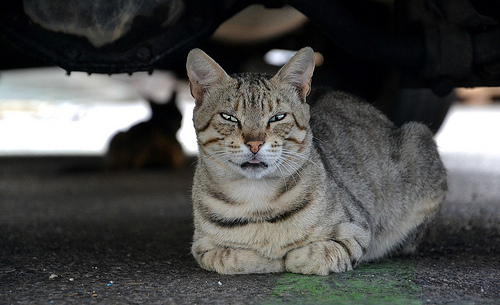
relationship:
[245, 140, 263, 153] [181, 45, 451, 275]
cat's nose on cat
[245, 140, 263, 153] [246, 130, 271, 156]
cat's nose on cat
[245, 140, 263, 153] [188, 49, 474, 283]
cat's nose on cat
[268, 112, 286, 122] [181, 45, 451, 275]
cat's eye on cat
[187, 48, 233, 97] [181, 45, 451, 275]
ear on cat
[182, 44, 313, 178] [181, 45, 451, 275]
head on cat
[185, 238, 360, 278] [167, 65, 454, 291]
feet are on cat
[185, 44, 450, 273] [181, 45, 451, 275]
cat fur on cat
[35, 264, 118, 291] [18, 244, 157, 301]
debris on asphalt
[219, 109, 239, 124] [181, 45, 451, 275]
eye of a cat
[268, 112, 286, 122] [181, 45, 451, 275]
cat's eye of a cat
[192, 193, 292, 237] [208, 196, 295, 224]
stripes on a fur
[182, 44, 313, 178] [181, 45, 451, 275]
head of a cat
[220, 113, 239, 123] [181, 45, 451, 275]
eye of a cat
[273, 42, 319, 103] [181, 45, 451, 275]
ear of a cat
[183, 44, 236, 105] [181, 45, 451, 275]
ear of a cat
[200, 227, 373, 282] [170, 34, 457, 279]
legs of a cat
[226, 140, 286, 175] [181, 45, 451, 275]
mouth of a cat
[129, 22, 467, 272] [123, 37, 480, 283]
body of a cat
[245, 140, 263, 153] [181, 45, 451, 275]
cat's nose of a cat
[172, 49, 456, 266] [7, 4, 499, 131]
cat under a car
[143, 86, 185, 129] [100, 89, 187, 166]
head of a cat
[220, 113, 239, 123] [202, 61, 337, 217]
eye of a cat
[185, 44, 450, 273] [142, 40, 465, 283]
cat fur of a cat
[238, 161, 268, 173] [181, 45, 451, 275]
mouth of a cat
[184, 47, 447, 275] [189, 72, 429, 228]
body of a cat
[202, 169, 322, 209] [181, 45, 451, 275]
neck of a cat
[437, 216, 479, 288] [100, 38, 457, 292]
shadows of a cat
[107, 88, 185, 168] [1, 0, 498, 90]
cat under a car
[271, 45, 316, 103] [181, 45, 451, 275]
ear on cat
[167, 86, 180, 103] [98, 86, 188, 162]
ear on cat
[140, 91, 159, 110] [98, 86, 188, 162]
ear on cat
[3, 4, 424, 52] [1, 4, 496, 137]
undercarriage attached to motor vehicle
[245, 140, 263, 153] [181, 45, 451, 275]
cat's nose of cat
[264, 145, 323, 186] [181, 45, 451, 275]
whiskers of cat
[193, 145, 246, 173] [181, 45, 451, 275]
whiskers of cat